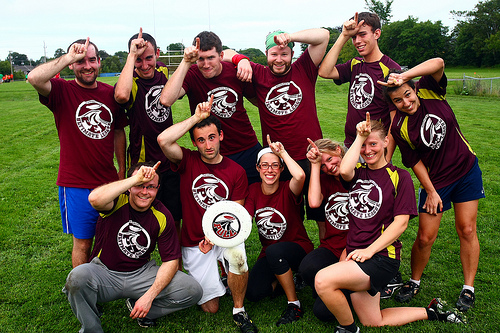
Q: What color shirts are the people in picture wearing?
A: Burgundy.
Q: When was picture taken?
A: In daylight.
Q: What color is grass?
A: Green.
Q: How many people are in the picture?
A: Eleven.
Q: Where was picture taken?
A: On school yard.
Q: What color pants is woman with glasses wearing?
A: Black.